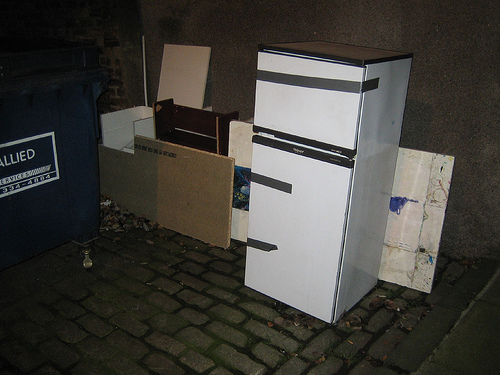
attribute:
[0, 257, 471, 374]
ground — tiled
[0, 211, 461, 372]
ground — tiled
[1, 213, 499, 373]
floor —  dirty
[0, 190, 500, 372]
floor —  dirty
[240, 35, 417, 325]
fridge —  white, white , black  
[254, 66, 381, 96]
tape —  gray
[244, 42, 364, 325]
door — taped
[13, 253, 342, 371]
walkway — gray   , brick 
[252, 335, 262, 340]
grout — dark , gray 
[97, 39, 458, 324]
debris — stacked 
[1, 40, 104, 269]
trash container — blue , large 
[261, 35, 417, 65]
top — black  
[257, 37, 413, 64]
trim — black  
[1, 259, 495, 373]
floor — brown , brick , stone 